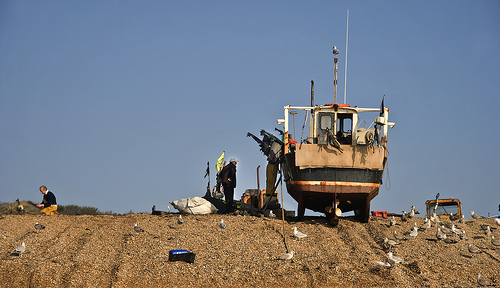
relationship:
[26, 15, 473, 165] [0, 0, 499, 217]
clouds in sky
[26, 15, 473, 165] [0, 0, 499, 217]
clouds is in sky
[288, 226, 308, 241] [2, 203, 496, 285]
bird is in sand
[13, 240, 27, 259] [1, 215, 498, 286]
bird is in sand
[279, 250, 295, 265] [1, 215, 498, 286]
bird is in sand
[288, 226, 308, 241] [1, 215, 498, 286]
bird is in sand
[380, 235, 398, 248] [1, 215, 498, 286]
bird is in sand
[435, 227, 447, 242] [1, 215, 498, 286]
bird is in sand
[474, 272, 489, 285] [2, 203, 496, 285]
bird is in sand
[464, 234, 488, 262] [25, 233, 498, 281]
bird is in sand